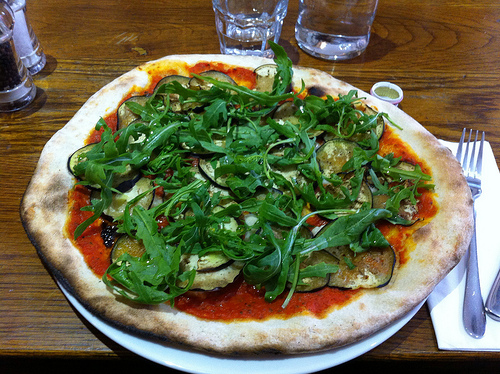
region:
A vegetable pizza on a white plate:
[41, 45, 448, 349]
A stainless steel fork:
[460, 117, 488, 337]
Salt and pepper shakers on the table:
[3, 1, 60, 122]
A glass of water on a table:
[300, 0, 377, 64]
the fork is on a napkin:
[443, 112, 489, 337]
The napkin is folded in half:
[433, 134, 498, 349]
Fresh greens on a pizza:
[126, 97, 354, 294]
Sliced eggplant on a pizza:
[187, 237, 239, 298]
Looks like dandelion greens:
[220, 161, 300, 246]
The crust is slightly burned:
[38, 251, 83, 298]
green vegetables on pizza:
[122, 79, 382, 297]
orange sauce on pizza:
[65, 86, 444, 319]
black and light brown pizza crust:
[68, 87, 460, 352]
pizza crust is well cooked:
[68, 67, 499, 368]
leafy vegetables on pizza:
[129, 88, 434, 328]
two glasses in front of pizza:
[197, 1, 397, 36]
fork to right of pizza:
[417, 96, 498, 276]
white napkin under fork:
[422, 152, 496, 355]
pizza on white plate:
[63, 70, 464, 350]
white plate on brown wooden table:
[75, 86, 438, 369]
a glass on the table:
[298, 0, 369, 51]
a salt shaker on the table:
[11, 0, 46, 77]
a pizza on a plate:
[55, 40, 474, 352]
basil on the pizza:
[159, 98, 371, 285]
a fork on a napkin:
[445, 128, 499, 333]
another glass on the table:
[211, 0, 273, 60]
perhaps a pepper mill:
[0, 4, 33, 104]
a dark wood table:
[416, 16, 472, 121]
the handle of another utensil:
[486, 263, 499, 323]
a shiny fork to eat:
[452, 128, 487, 338]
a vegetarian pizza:
[16, 53, 472, 351]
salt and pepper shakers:
[0, 1, 50, 106]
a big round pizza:
[18, 52, 476, 358]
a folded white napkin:
[425, 132, 497, 352]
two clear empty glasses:
[207, 0, 377, 55]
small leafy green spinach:
[88, 60, 403, 301]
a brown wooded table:
[0, 0, 497, 350]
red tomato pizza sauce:
[67, 65, 432, 316]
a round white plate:
[36, 260, 467, 371]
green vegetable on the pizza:
[72, 83, 413, 294]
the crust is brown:
[19, 45, 479, 364]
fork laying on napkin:
[431, 96, 498, 338]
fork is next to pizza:
[439, 115, 499, 341]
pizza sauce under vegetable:
[67, 80, 435, 312]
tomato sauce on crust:
[123, 46, 170, 78]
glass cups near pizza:
[210, 0, 371, 62]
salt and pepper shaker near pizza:
[0, 0, 56, 100]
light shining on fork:
[447, 155, 497, 201]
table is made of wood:
[1, 2, 496, 353]